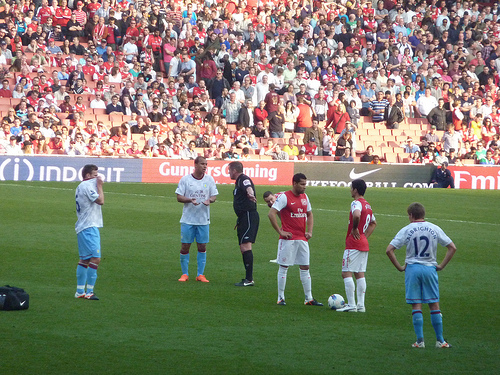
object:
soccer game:
[0, 160, 492, 373]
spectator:
[297, 97, 315, 141]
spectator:
[252, 120, 269, 139]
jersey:
[271, 190, 311, 238]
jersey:
[73, 177, 104, 232]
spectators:
[0, 2, 485, 163]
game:
[4, 157, 499, 372]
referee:
[226, 160, 263, 290]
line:
[131, 182, 169, 209]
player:
[267, 171, 322, 306]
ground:
[314, 187, 337, 258]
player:
[59, 161, 107, 298]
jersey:
[373, 221, 467, 271]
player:
[333, 177, 379, 312]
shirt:
[270, 187, 316, 241]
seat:
[362, 120, 374, 129]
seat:
[379, 126, 393, 136]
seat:
[403, 127, 417, 137]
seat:
[359, 133, 371, 141]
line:
[376, 206, 406, 220]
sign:
[4, 158, 499, 187]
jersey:
[178, 177, 231, 220]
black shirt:
[230, 172, 260, 216]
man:
[425, 154, 454, 193]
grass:
[4, 179, 498, 373]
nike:
[349, 168, 381, 178]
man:
[175, 157, 217, 284]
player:
[264, 191, 285, 209]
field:
[2, 184, 494, 371]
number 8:
[359, 213, 370, 230]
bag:
[0, 280, 35, 315]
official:
[226, 162, 258, 287]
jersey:
[227, 175, 266, 217]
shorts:
[168, 220, 219, 244]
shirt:
[220, 172, 264, 215]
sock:
[74, 268, 96, 300]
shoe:
[171, 273, 194, 284]